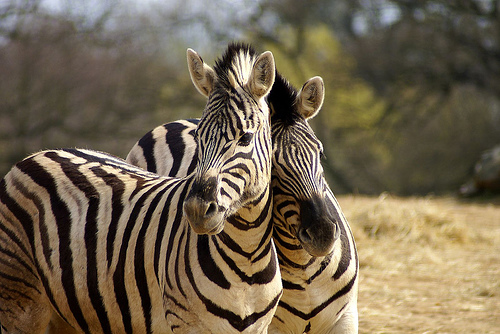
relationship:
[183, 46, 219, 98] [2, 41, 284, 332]
ear on zebra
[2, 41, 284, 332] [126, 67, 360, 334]
zebra next to zebra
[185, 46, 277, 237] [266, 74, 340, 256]
head touching head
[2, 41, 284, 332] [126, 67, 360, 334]
zebra standing next to zebra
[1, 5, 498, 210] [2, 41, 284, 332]
trees behind zebra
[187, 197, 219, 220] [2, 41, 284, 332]
nose on zebra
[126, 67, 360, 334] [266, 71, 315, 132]
zebra has black mane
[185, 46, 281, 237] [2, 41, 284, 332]
head on zebra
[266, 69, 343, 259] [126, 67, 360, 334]
head on zebra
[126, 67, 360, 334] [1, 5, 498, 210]
zebra in front of trees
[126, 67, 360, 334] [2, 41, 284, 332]
zebra leaning on zebra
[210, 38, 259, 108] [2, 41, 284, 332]
mane on zebra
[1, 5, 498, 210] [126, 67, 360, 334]
trees behind zebra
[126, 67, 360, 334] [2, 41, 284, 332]
zebra huddling next to zebra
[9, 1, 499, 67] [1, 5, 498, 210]
sky behind trees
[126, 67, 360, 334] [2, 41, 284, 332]
zebra standing next to zebra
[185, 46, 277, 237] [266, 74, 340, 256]
head together with head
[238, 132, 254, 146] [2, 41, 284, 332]
eye on zebra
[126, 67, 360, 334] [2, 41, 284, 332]
zebra leaning against zebra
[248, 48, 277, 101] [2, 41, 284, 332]
ear on zebra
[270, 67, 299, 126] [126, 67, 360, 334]
black mane on zebra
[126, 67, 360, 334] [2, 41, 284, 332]
zebra touching zebra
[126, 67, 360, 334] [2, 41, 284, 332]
zebra nuzzles other zebra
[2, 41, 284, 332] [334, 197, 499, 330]
zebra on grass